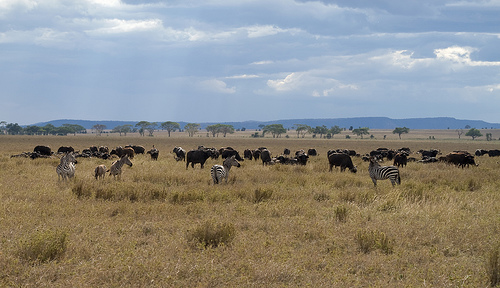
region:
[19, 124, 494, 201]
animals on a prarie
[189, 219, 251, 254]
green grass on a prarie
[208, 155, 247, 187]
zebra in the grass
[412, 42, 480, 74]
white cloud in the sky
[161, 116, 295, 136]
trees in the distance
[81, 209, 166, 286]
brown grass of a plain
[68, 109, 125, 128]
mountains in the distance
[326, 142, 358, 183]
animal grazing in grass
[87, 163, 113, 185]
zebra grazing in grass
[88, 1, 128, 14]
light shining from the sun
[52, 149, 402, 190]
zebras standing in the foreground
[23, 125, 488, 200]
herd of different animals standing together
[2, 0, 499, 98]
clouds covering the sky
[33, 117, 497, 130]
mountains in the far distance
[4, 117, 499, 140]
line of trees in front of mountains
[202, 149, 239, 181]
zebra standing in the center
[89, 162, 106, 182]
zebra grazing on the grass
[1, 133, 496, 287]
dried grass animals are standing in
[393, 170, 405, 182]
black tail of zebra on the right side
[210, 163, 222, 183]
black tail of zebra in the middle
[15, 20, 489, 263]
picture of animals in the wild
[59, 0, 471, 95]
sky covered with grey clouds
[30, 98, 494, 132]
mountain range in the distance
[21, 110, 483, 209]
animals grazing in a large field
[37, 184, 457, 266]
field full of tall grass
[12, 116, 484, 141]
row of trees in the distance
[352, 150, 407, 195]
black and white zebra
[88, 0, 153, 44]
light shining through clouds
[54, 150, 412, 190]
five zebras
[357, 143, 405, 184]
zebra with black and white stripes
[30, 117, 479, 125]
a lot of mountains in the distance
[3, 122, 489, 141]
many trees in the distance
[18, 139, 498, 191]
some zebras mixed with buffalos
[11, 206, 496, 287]
a lot of grass in the field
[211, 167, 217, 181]
one zebra tail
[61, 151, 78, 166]
the head of a zebra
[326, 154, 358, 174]
a buffalo eating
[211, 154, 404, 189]
two zebras watching around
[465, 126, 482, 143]
a green tree far away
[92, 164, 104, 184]
a zebra eating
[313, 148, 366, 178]
animal in the field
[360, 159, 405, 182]
animal in the field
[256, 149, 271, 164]
animal in the field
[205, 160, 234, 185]
animal in the field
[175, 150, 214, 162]
animal in the field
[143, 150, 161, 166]
animal in the field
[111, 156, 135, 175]
animal in the field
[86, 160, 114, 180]
animal in the field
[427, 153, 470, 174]
animal in the field